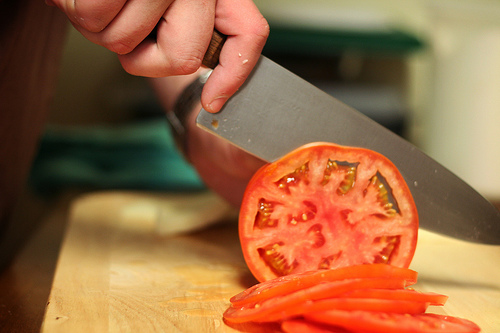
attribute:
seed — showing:
[374, 180, 387, 192]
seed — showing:
[297, 209, 310, 223]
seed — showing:
[285, 215, 300, 226]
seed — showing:
[260, 210, 276, 218]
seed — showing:
[261, 247, 277, 257]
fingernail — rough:
[200, 83, 231, 121]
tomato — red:
[232, 144, 472, 326]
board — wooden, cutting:
[47, 193, 223, 329]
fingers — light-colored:
[55, 2, 275, 111]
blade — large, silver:
[212, 59, 498, 255]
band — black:
[168, 63, 217, 162]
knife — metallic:
[342, 106, 429, 178]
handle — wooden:
[153, 17, 225, 72]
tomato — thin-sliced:
[236, 140, 419, 282]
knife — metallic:
[190, 59, 498, 241]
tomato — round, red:
[223, 138, 480, 330]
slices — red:
[298, 261, 365, 300]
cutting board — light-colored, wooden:
[50, 119, 499, 329]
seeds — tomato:
[327, 160, 419, 272]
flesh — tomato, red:
[349, 149, 409, 267]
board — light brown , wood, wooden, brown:
[37, 183, 493, 327]